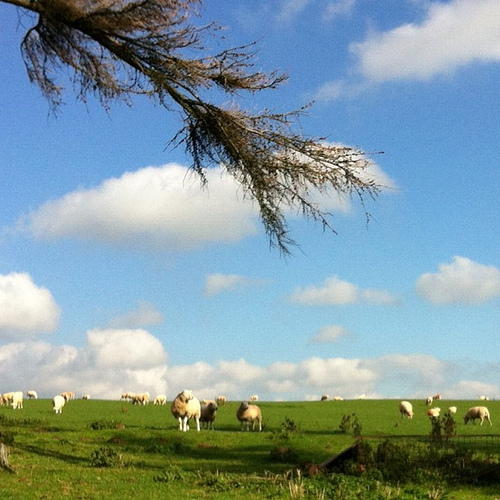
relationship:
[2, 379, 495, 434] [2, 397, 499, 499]
sheep in field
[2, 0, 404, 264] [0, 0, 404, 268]
leaves on tree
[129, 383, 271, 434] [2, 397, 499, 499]
sheep grazing in field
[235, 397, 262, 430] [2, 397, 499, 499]
sheep grazing in field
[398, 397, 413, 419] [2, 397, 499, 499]
sheep grazing in field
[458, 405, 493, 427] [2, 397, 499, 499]
sheep grazing in field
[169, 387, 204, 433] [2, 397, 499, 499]
sheep grazing in field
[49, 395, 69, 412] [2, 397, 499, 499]
sheep grazing in field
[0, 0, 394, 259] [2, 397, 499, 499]
branch hanging over field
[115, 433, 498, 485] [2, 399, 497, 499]
shadow on ground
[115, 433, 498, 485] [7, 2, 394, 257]
shadow of branch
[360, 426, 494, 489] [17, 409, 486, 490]
fence in field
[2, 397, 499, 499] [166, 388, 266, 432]
field in sheep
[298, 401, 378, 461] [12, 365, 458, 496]
bushes on field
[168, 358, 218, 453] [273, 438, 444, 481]
sheep in field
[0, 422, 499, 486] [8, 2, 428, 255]
shadow from tree